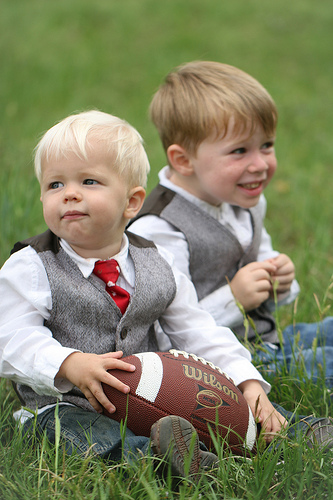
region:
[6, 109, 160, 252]
a baby with blonde hair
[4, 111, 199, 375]
a baby wearing a tie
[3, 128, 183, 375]
a baby wearing a vest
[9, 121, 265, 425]
a baby wearing a longsleeve shirt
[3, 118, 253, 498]
a baby holding a football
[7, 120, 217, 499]
a baby sitting on the grass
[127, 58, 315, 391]
a small boy sitting on the grass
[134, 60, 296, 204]
a small boy with brown hair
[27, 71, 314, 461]
two boys sitting on the grass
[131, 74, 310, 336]
a small boy wearing a vest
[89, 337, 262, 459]
the football is brown and white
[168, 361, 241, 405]
the letters are gold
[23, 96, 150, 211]
the boy`s hair is blonde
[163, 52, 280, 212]
the boy is smiling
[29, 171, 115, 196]
the eyes are open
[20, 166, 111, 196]
the eyes are looking left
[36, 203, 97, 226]
the mouth is closed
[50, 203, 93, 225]
the lips are pink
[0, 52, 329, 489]
two boys sitting in grass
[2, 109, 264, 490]
Boy holding football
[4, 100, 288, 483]
Boy holding football in grass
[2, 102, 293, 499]
boy wearing red tie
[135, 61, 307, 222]
boy smiling in background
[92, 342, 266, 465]
Brown and white Wilson football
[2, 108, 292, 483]
Boy with light blond hair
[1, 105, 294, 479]
Boy is holding a football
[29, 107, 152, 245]
Boy has blonde hair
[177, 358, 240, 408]
"Wilson" written on a football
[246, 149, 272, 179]
Nose on boy's face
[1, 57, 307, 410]
Two boys wearing gray vests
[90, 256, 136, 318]
A red colored tie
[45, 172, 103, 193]
A pair of eyes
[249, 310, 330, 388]
A pair of blue jeans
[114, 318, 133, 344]
A button on a gray vest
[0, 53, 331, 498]
Two boys sitting on the grass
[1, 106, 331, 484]
Young boy with blond hair and blue eyes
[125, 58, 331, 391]
Young boy with red hair sitting in grass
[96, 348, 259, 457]
Brown and white football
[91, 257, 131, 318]
Red tie on little boy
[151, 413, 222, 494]
Bottom of little boy's shoe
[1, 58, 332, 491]
Two young boys sitting in a grassy field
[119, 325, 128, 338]
Button on boy's gray vest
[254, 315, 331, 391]
Blue jeans on red haired boy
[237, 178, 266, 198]
Big smile on red haired boy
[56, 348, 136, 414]
Little boy's right hand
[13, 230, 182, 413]
the vest is gray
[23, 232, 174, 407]
the vest is gray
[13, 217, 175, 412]
the vest is gray